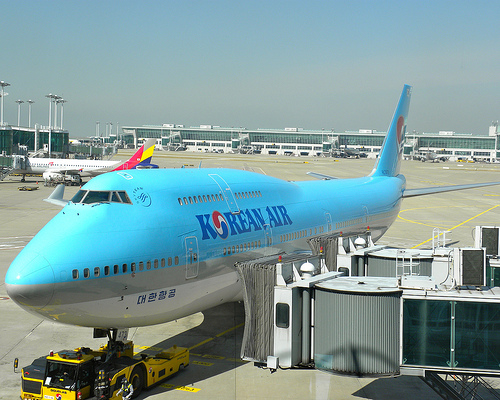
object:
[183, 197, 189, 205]
windows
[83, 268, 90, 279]
windows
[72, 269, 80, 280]
windows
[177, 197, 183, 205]
windows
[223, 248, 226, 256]
windows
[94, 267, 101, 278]
windows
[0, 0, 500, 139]
sky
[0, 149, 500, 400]
ground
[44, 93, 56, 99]
lights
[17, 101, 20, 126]
light poles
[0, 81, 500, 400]
airport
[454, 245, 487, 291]
ac unit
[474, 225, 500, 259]
ac unit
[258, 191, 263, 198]
window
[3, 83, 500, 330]
plane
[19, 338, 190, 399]
cart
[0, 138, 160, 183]
jet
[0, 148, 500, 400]
tarmac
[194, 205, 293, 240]
writing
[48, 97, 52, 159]
lamp pole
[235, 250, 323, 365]
walkway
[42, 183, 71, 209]
wing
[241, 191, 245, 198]
windows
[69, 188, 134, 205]
cockpit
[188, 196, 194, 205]
window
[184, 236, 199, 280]
door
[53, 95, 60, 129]
pole light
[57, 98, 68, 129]
pole light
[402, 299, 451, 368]
glass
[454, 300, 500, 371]
glass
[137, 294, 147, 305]
letters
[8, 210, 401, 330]
side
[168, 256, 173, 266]
windows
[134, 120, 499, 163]
building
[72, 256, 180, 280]
row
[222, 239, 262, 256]
row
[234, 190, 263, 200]
row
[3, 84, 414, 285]
top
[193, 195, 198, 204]
windows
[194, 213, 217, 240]
letters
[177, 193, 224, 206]
levels